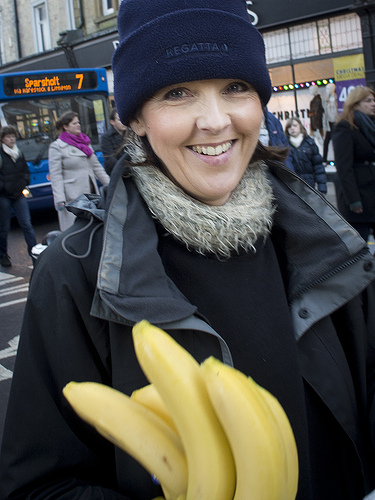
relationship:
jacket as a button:
[0, 151, 374, 500] [297, 305, 311, 324]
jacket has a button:
[0, 151, 374, 500] [363, 261, 373, 273]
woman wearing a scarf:
[1, 1, 374, 498] [128, 132, 273, 255]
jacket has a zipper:
[0, 151, 374, 500] [288, 243, 370, 316]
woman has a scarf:
[1, 1, 374, 498] [128, 132, 273, 255]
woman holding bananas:
[1, 1, 374, 498] [62, 319, 298, 500]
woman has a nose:
[1, 1, 374, 498] [194, 95, 231, 135]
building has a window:
[1, 0, 128, 71] [28, 1, 55, 54]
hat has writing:
[111, 0, 271, 125] [162, 38, 232, 61]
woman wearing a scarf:
[45, 110, 114, 234] [56, 128, 96, 157]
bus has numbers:
[0, 67, 120, 231] [71, 75, 90, 93]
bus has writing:
[0, 67, 120, 231] [12, 77, 74, 98]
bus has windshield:
[0, 67, 120, 231] [30, 134, 52, 168]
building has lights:
[171, 0, 374, 176] [268, 79, 339, 99]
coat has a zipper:
[0, 151, 374, 500] [288, 243, 370, 316]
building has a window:
[1, 0, 128, 71] [97, 0, 120, 25]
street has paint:
[0, 197, 108, 439] [0, 267, 29, 387]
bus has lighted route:
[0, 67, 120, 231] [4, 72, 99, 94]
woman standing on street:
[1, 1, 374, 498] [0, 197, 108, 439]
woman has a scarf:
[45, 110, 114, 234] [56, 128, 96, 157]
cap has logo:
[111, 0, 271, 125] [162, 38, 232, 61]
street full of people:
[0, 197, 108, 439] [0, 90, 375, 324]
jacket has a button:
[0, 151, 374, 500] [297, 305, 311, 324]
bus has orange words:
[0, 67, 120, 231] [12, 77, 74, 98]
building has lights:
[171, 0, 374, 176] [272, 78, 334, 93]